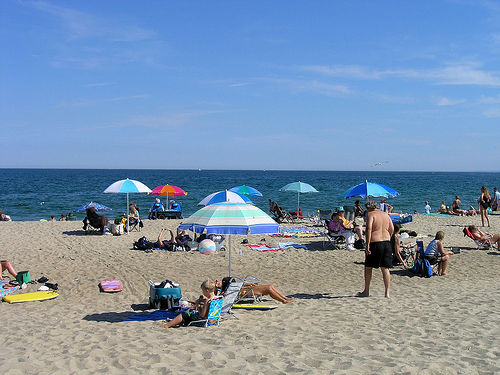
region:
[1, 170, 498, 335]
people on the beach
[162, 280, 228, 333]
little kid sitting in a small chair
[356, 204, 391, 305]
man walking on the sand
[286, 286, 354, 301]
shadow on the sand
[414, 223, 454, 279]
woman sitting in a chair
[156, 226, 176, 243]
arms in the air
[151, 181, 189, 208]
pink and orange umbrella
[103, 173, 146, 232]
blue and white umbrella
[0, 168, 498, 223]
dark blue body of water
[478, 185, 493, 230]
woman standing on the beach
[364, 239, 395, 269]
Man wearing shorts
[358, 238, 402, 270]
Man is wearing shorts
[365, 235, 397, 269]
Man wearing black shorts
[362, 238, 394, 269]
Man is wearing black shorts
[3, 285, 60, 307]
Boogie board on the sand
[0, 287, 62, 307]
Boogie board is on the sand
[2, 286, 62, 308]
Yellow boogie board on the sand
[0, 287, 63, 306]
Yellow boogie board is on the sand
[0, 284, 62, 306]
Boogie board on the beach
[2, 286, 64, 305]
Yellow boogie board is on the beach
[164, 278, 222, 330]
boy sitting on a small chair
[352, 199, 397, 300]
man walking on the beach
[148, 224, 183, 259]
person laying on a towel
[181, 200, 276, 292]
umbrella sticking in the sand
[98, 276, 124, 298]
board laying on the sand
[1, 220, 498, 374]
shoreline is covered in sand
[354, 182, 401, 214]
the head of a man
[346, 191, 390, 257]
the arm of a man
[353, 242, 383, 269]
the hand of a man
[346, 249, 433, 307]
the legs of a man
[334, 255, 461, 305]
the feet of a man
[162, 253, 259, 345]
a boy sitting in a chair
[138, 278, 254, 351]
a boy on the sand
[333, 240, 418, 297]
a man wearing shorts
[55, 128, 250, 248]
water near a beach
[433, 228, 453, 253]
the head of a woman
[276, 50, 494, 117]
clouds in the sky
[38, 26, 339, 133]
the clear blue sky above the water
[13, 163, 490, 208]
the water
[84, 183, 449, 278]
umbrellas on the beach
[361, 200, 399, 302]
a man standing on the beach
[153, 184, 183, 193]
a pink umbrella on the beach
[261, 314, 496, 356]
sand on the beach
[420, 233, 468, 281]
a person sitting in a chair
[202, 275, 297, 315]
a person laying down on the beach